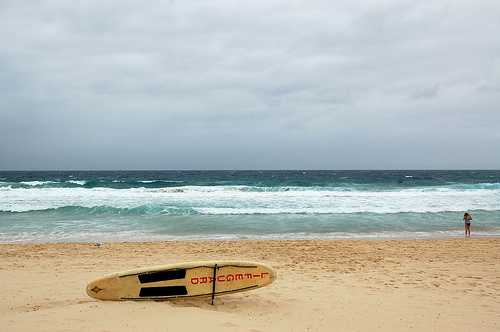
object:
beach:
[0, 226, 500, 332]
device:
[84, 261, 276, 303]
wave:
[0, 176, 500, 215]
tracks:
[0, 239, 500, 302]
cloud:
[0, 2, 497, 168]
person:
[285, 188, 289, 192]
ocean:
[0, 169, 500, 238]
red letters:
[190, 273, 268, 285]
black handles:
[211, 263, 217, 305]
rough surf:
[0, 187, 80, 213]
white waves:
[198, 185, 236, 202]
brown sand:
[0, 239, 500, 332]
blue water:
[0, 171, 500, 187]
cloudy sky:
[0, 1, 500, 168]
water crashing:
[241, 187, 297, 215]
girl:
[462, 212, 472, 235]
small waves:
[150, 203, 204, 217]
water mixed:
[278, 232, 332, 240]